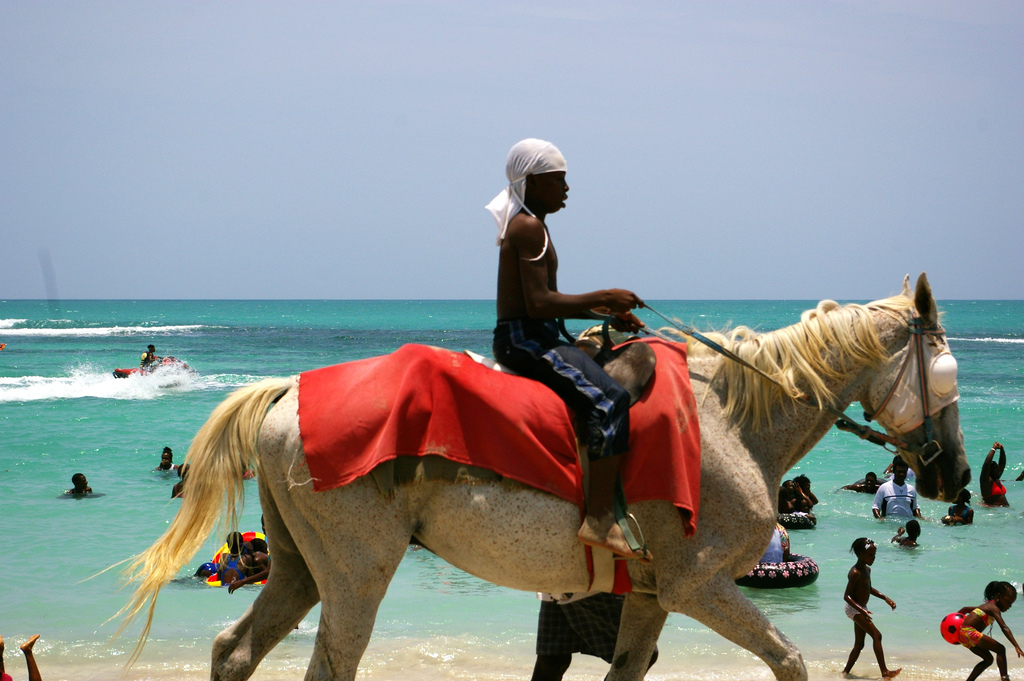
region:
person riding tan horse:
[213, 110, 956, 677]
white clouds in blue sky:
[55, 31, 139, 115]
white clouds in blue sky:
[459, 72, 526, 118]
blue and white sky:
[229, 65, 363, 222]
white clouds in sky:
[64, 47, 356, 222]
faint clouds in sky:
[64, 50, 349, 265]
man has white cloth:
[455, 126, 569, 244]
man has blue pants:
[500, 185, 649, 486]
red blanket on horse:
[324, 328, 768, 564]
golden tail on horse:
[105, 365, 283, 587]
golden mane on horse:
[551, 294, 865, 488]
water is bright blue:
[3, 419, 162, 574]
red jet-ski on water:
[98, 325, 198, 396]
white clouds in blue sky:
[84, 119, 151, 183]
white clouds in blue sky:
[629, 75, 728, 177]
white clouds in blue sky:
[380, 7, 494, 74]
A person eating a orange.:
[835, 522, 868, 624]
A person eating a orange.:
[116, 276, 200, 432]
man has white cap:
[500, 148, 605, 251]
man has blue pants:
[535, 340, 631, 496]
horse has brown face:
[868, 352, 966, 502]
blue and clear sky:
[120, 90, 291, 215]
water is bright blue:
[276, 258, 390, 375]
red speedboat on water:
[111, 314, 178, 379]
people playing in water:
[39, 413, 227, 521]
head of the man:
[438, 95, 650, 226]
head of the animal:
[802, 252, 1022, 537]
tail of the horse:
[44, 307, 336, 602]